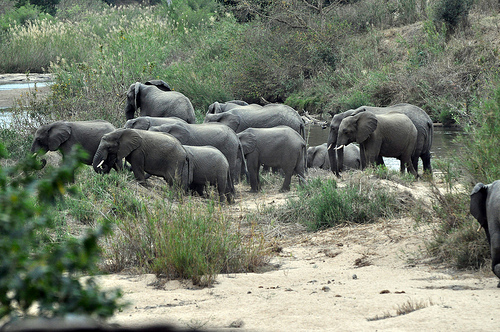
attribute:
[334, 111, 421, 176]
elephant — straggling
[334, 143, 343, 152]
tusk — ivory, white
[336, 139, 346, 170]
trunk — long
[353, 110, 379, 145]
ear — large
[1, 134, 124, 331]
bush — in the foreground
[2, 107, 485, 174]
water — calm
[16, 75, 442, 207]
elephants — in a herd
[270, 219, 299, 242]
stick — dried